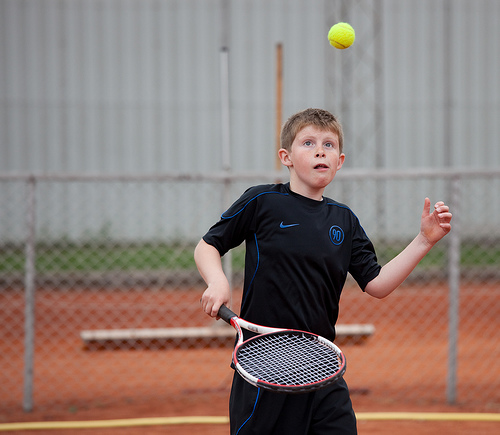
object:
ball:
[326, 21, 356, 50]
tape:
[199, 297, 239, 325]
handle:
[216, 303, 242, 329]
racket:
[199, 297, 346, 394]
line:
[2, 411, 500, 431]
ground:
[0, 279, 499, 434]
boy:
[193, 108, 453, 434]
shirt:
[201, 183, 384, 374]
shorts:
[229, 363, 359, 434]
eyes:
[303, 141, 314, 147]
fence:
[0, 168, 500, 413]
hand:
[201, 285, 231, 321]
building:
[0, 0, 500, 241]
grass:
[0, 235, 500, 269]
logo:
[280, 221, 300, 229]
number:
[332, 228, 337, 240]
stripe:
[235, 386, 261, 434]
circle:
[329, 225, 345, 247]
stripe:
[241, 232, 261, 311]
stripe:
[220, 190, 290, 219]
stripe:
[325, 202, 371, 242]